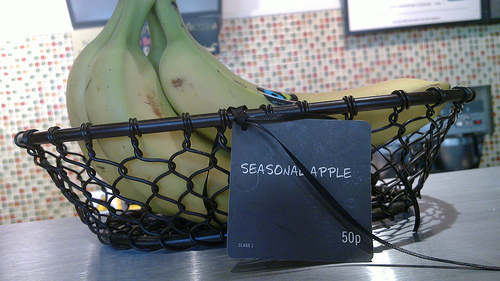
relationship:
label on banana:
[258, 88, 290, 107] [154, 3, 454, 149]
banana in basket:
[154, 3, 454, 149] [15, 85, 477, 252]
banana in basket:
[83, 3, 229, 223] [15, 85, 477, 252]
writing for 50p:
[240, 161, 351, 179] [339, 227, 363, 246]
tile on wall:
[253, 19, 277, 38] [4, 7, 499, 227]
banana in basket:
[65, 0, 229, 227] [15, 85, 477, 252]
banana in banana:
[154, 3, 454, 149] [65, 0, 229, 227]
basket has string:
[15, 85, 477, 252] [232, 106, 498, 276]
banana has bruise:
[154, 3, 454, 149] [169, 78, 184, 87]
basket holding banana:
[15, 85, 477, 252] [65, 0, 229, 227]